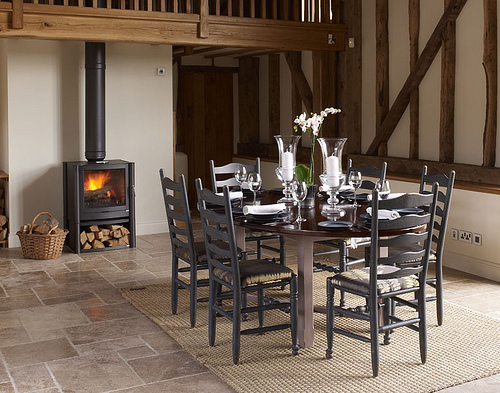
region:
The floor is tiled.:
[33, 293, 128, 391]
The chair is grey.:
[192, 193, 293, 388]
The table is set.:
[237, 133, 389, 265]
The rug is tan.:
[249, 339, 451, 387]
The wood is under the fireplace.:
[76, 223, 140, 253]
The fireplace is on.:
[53, 126, 113, 184]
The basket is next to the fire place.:
[7, 209, 87, 299]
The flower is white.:
[292, 92, 346, 133]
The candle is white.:
[313, 136, 361, 233]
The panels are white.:
[367, 29, 491, 191]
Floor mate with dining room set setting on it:
[102, 251, 497, 387]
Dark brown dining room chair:
[320, 186, 442, 379]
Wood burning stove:
[55, 155, 145, 256]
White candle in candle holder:
[318, 146, 350, 227]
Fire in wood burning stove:
[81, 170, 122, 205]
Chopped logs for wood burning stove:
[80, 220, 135, 252]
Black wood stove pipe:
[71, 36, 118, 163]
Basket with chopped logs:
[8, 202, 70, 259]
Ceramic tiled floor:
[2, 225, 497, 391]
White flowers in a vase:
[278, 94, 343, 216]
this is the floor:
[28, 275, 93, 371]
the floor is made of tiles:
[30, 275, 92, 367]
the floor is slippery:
[37, 281, 104, 382]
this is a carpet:
[273, 352, 308, 390]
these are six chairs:
[160, 160, 468, 371]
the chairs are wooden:
[165, 194, 232, 240]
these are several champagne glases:
[235, 167, 370, 221]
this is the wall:
[117, 89, 148, 122]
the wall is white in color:
[16, 90, 52, 150]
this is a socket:
[453, 226, 483, 253]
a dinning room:
[66, 86, 498, 391]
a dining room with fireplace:
[54, 85, 473, 388]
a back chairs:
[143, 93, 467, 390]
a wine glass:
[286, 176, 316, 225]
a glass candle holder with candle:
[310, 132, 349, 219]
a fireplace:
[17, 130, 141, 265]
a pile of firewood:
[18, 205, 141, 262]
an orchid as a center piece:
[290, 98, 340, 210]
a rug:
[189, 359, 261, 390]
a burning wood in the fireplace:
[81, 173, 122, 208]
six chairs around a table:
[151, 133, 473, 381]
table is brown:
[214, 171, 433, 253]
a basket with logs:
[10, 205, 71, 270]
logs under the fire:
[74, 219, 134, 258]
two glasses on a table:
[229, 160, 273, 215]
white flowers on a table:
[286, 94, 347, 206]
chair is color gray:
[328, 177, 448, 373]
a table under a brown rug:
[113, 127, 498, 385]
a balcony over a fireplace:
[8, 3, 337, 62]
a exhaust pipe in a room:
[76, 42, 118, 169]